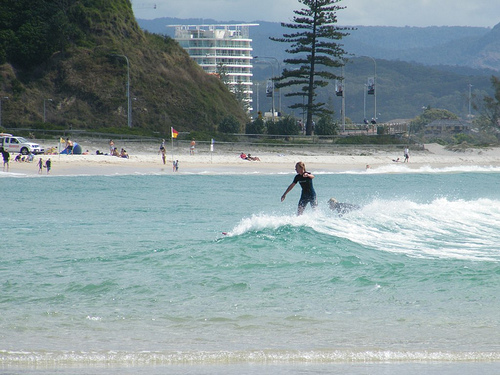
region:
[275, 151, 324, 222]
person standing on a surf board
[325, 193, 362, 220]
person in the water behind a wave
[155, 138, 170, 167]
person walking on the beach near the water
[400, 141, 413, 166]
person walking on the beach near the water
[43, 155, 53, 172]
person walking on the beach near the water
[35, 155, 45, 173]
person walking on the beach near the water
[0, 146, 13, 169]
person walking on the beach near the water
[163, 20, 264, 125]
large building near the beach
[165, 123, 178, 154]
red and yellow flag on a pole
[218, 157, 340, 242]
A person is on a surfboard.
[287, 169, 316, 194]
A person is wearing a black and white top.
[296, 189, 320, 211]
A person is wearing dark shorts.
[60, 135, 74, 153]
A male wearing shorts is on a beach.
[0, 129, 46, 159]
A vehicle is on a beach.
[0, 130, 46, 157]
The color of a vehicle is white and orange.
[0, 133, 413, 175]
People are on a beach.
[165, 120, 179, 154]
A flag is flying on a beach.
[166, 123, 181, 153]
The colors of a flag are red, white, and yellow.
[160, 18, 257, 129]
A white building is in the background.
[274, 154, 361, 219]
the people ride the wave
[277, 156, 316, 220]
the person surfing on the water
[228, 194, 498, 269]
the water splashing into the air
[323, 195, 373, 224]
the man laying in the water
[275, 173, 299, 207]
the arm of the girl out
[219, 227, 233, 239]
the tip of the surfboard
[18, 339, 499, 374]
the tide coming into the beach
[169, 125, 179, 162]
the flag on the beach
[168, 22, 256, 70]
the building behind the hill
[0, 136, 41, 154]
the white truck on the beach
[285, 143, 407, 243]
people in the water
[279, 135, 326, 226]
girl on surfboard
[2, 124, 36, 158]
truck parked on beach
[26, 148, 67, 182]
walking along the beach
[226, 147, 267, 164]
laying on the sand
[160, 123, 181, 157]
flag in the sand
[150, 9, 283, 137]
white building behind the hill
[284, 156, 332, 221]
girl is wearing a wetsuit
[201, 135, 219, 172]
signs on the beach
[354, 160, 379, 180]
person in the water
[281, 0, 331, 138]
a tall evergreen tree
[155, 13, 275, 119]
a tall white hotel building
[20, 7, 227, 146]
the edge of a small mountain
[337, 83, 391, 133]
street signs in the distance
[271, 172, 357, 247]
a guy riding a small wave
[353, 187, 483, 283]
a small wave in the ocean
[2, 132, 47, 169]
a truck parked on the beach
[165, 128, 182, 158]
a small flag in the beach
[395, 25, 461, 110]
mountains in the distance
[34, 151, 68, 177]
people that are standing on the beach